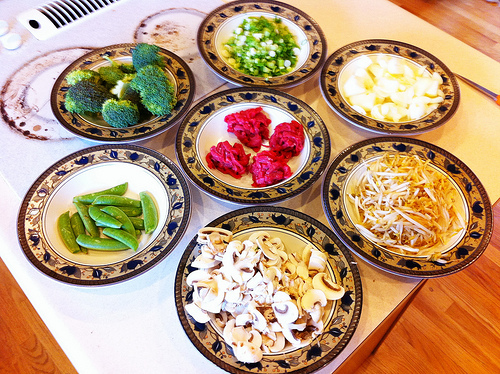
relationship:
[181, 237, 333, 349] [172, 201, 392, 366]
mushroom in bowl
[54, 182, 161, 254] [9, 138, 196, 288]
snap peas in bowl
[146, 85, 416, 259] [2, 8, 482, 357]
food on counter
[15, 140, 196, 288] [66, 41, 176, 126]
bowl of broccoli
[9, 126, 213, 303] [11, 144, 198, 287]
bowl has floral print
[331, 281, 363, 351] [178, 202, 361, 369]
trim around bowl